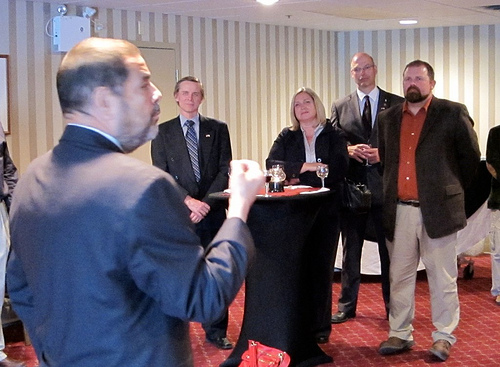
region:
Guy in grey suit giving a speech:
[18, 27, 263, 365]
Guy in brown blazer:
[375, 55, 473, 354]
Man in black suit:
[153, 78, 237, 345]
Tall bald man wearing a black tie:
[317, 44, 403, 321]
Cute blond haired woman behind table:
[269, 85, 352, 188]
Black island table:
[203, 175, 336, 365]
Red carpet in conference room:
[10, 263, 499, 362]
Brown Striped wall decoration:
[0, 0, 497, 252]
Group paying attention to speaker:
[141, 50, 482, 350]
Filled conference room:
[3, 2, 499, 362]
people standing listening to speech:
[146, 39, 477, 365]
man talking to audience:
[0, 28, 282, 355]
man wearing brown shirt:
[352, 48, 498, 225]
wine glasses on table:
[262, 157, 351, 209]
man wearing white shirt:
[313, 45, 406, 189]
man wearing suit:
[157, 61, 262, 216]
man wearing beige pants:
[372, 190, 482, 357]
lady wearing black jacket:
[260, 91, 346, 192]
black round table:
[203, 169, 360, 365]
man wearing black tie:
[339, 78, 396, 158]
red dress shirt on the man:
[396, 98, 431, 200]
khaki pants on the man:
[385, 200, 459, 345]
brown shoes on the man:
[376, 330, 451, 359]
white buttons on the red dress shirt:
[403, 125, 415, 180]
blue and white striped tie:
[182, 116, 202, 182]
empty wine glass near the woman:
[313, 162, 329, 189]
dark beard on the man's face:
[403, 83, 430, 103]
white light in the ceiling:
[394, 16, 419, 26]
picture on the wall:
[0, 50, 12, 137]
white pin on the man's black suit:
[203, 132, 211, 138]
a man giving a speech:
[15, 42, 303, 359]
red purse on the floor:
[231, 337, 280, 364]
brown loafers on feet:
[374, 332, 454, 361]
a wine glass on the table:
[313, 162, 330, 189]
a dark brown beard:
[403, 85, 423, 100]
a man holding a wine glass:
[346, 48, 384, 313]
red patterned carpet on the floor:
[464, 305, 491, 362]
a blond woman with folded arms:
[269, 102, 342, 188]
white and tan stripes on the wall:
[198, 29, 275, 111]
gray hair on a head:
[64, 49, 116, 85]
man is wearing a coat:
[355, 100, 456, 260]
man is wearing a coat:
[334, 73, 394, 205]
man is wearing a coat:
[9, 120, 231, 363]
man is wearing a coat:
[160, 113, 241, 213]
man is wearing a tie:
[348, 90, 384, 152]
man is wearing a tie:
[168, 110, 208, 180]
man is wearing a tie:
[341, 77, 394, 172]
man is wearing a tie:
[188, 121, 241, 235]